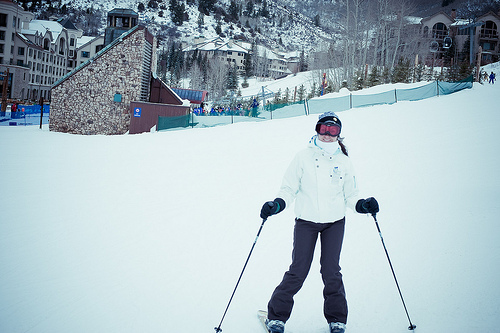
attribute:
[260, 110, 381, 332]
woman — smiling, happy, posing, skiing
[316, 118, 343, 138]
goggles — orange, protective, pink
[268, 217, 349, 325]
pants — black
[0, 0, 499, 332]
snow — white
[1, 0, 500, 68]
mountains — snow covered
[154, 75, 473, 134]
fence — green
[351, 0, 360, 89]
tree — bare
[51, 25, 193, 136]
building — interesting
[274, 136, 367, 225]
coat — white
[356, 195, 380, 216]
hand — gloved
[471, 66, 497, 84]
kids — playing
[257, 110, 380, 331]
skier — female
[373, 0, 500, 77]
ski lodge — large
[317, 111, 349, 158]
hair — dark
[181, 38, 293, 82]
apartments — residential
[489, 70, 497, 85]
person — walking uphill